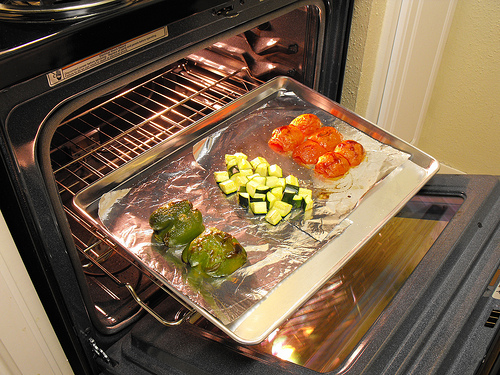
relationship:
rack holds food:
[45, 60, 267, 330] [147, 113, 375, 283]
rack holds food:
[50, 63, 268, 335] [147, 113, 375, 283]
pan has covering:
[69, 71, 443, 346] [116, 106, 392, 278]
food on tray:
[150, 113, 368, 278] [71, 74, 440, 346]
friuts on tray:
[148, 199, 249, 278] [71, 74, 440, 346]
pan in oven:
[69, 71, 443, 346] [1, 1, 497, 373]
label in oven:
[40, 20, 180, 94] [1, 1, 497, 373]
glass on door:
[311, 223, 428, 320] [99, 174, 500, 374]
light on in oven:
[206, 40, 303, 79] [1, 1, 497, 373]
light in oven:
[188, 38, 280, 76] [4, 10, 410, 370]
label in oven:
[45, 25, 169, 89] [6, 28, 483, 370]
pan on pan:
[268, 113, 368, 178] [69, 71, 443, 346]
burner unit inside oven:
[71, 228, 132, 277] [13, 0, 328, 347]